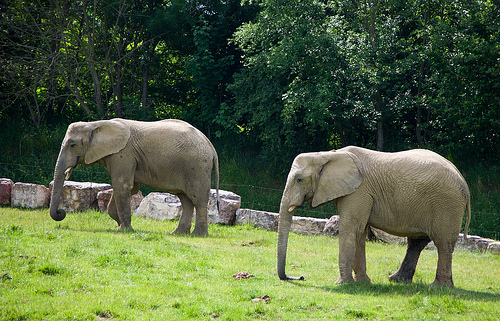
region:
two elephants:
[26, 75, 496, 306]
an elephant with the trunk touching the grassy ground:
[261, 130, 469, 309]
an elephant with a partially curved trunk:
[36, 97, 224, 261]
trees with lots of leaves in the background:
[76, 8, 479, 114]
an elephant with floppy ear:
[307, 149, 373, 220]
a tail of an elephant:
[208, 147, 228, 217]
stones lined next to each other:
[213, 196, 347, 241]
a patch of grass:
[61, 265, 139, 301]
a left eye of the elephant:
[288, 165, 309, 190]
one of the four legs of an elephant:
[428, 205, 472, 320]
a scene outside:
[17, 21, 465, 306]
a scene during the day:
[10, 20, 498, 300]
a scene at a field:
[9, 21, 484, 303]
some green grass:
[5, 200, 486, 320]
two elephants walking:
[25, 107, 495, 292]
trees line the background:
[5, 5, 499, 183]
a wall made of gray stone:
[6, 154, 498, 291]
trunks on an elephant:
[37, 114, 85, 236]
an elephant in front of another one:
[37, 97, 247, 272]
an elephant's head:
[256, 141, 367, 298]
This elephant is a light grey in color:
[292, 122, 460, 286]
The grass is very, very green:
[147, 247, 212, 313]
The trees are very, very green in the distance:
[322, 40, 410, 115]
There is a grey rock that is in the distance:
[243, 200, 270, 235]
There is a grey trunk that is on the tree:
[136, 65, 170, 132]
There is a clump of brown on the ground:
[231, 262, 253, 291]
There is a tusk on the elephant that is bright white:
[287, 196, 299, 221]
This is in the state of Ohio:
[100, 37, 358, 307]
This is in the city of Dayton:
[115, 43, 340, 305]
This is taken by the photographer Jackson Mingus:
[79, 57, 398, 297]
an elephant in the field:
[50, 97, 232, 249]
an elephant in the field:
[265, 120, 485, 285]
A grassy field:
[0, 200, 485, 315]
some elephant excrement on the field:
[245, 285, 270, 305]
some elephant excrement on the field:
[225, 265, 250, 280]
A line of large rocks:
[0, 170, 497, 252]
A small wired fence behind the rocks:
[15, 145, 495, 235]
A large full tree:
[245, 0, 491, 140]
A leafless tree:
[0, 0, 186, 118]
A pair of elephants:
[48, 106, 468, 289]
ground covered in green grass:
[135, 266, 203, 299]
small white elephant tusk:
[286, 197, 301, 218]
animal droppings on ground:
[221, 259, 267, 313]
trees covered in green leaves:
[291, 3, 498, 108]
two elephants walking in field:
[41, 109, 476, 297]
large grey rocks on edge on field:
[223, 200, 275, 227]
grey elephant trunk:
[266, 211, 311, 293]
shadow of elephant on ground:
[340, 271, 497, 304]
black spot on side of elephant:
[111, 144, 129, 165]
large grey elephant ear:
[86, 121, 138, 168]